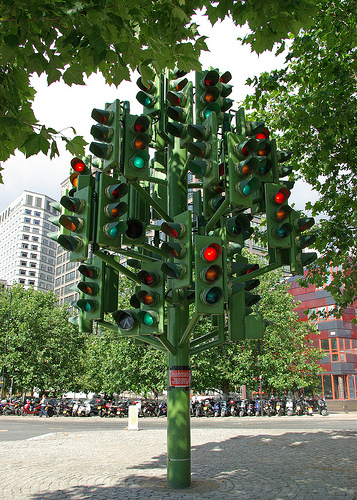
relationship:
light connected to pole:
[46, 69, 317, 489] [162, 313, 191, 490]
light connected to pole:
[46, 69, 317, 489] [204, 195, 229, 234]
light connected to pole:
[46, 69, 317, 489] [163, 72, 196, 490]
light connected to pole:
[226, 133, 264, 205] [165, 356, 197, 491]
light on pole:
[46, 69, 317, 489] [165, 122, 189, 487]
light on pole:
[46, 69, 317, 489] [152, 338, 197, 472]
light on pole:
[46, 69, 317, 489] [161, 338, 192, 484]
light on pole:
[46, 69, 317, 489] [166, 137, 188, 489]